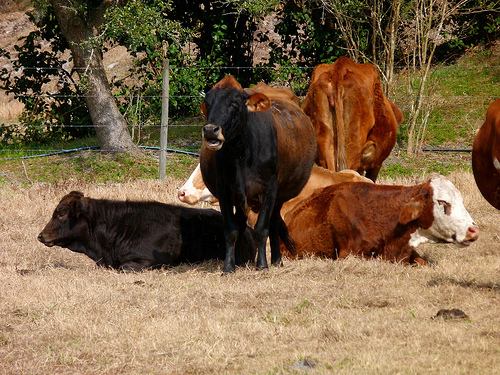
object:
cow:
[298, 55, 404, 184]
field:
[0, 0, 499, 375]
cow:
[35, 190, 259, 276]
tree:
[0, 0, 149, 163]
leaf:
[41, 92, 78, 122]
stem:
[43, 89, 61, 107]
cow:
[468, 97, 500, 213]